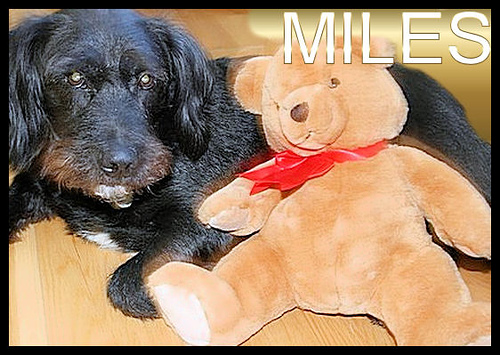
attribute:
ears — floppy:
[1, 11, 228, 172]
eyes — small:
[61, 65, 155, 95]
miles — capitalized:
[275, 11, 493, 63]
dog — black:
[5, 10, 484, 320]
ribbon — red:
[234, 136, 400, 198]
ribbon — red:
[239, 140, 397, 199]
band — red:
[235, 136, 390, 199]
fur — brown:
[291, 227, 361, 265]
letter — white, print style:
[282, 10, 337, 65]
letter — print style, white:
[342, 11, 354, 65]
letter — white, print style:
[359, 12, 394, 64]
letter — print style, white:
[400, 10, 443, 65]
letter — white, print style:
[448, 10, 484, 66]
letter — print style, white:
[342, 10, 352, 64]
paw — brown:
[142, 256, 242, 346]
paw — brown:
[402, 300, 484, 345]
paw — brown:
[194, 185, 266, 237]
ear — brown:
[232, 55, 272, 116]